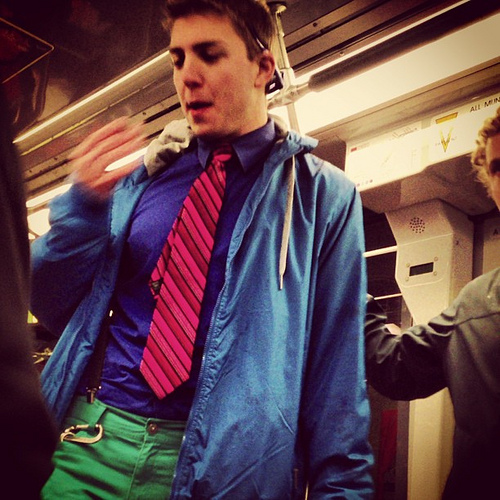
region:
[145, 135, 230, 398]
a pink and red striped tie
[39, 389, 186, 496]
a pair of green denim pants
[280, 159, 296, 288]
a white lace from a jacket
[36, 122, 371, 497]
a blue hooded jacket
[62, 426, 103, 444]
a metal caribeaner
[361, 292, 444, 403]
a man's outstretch right arm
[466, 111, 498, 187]
curly blonde hair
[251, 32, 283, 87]
a pen over a man's ear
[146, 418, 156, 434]
a metal button on the front of a man's pants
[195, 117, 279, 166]
the collar on a man's purple shirt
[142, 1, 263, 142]
the head of a young man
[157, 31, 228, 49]
the eyebrows of a young man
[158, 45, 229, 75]
the eyes of a young man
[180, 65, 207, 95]
the nose of a young man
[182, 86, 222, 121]
the mouth of a young man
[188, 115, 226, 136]
the chin of a young man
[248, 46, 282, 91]
the ear of a young man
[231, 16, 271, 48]
the hair of a young man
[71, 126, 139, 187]
the hand of a young man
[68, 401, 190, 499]
the pants of a young man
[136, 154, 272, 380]
the man is wearing a striped tie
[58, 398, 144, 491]
the man is wearing green pants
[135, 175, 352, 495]
the man is wearing a blue shirt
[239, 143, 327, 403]
the man has a white string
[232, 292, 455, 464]
the man is wearing a blue jacket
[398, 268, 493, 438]
the man is behind him in a black jacket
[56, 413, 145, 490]
a clip is on the pants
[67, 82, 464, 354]
the man is on a subway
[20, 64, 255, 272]
metal bars are above the man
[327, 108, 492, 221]
a beige wall is atop the train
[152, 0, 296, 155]
head of a person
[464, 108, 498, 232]
of a person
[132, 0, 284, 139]
a head of a person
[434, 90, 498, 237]
a head of a person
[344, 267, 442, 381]
arm of a person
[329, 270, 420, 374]
an arm of a person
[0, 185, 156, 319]
arm of a person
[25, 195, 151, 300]
an arm of a person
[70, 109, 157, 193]
hand of a person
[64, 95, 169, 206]
a hand of a person